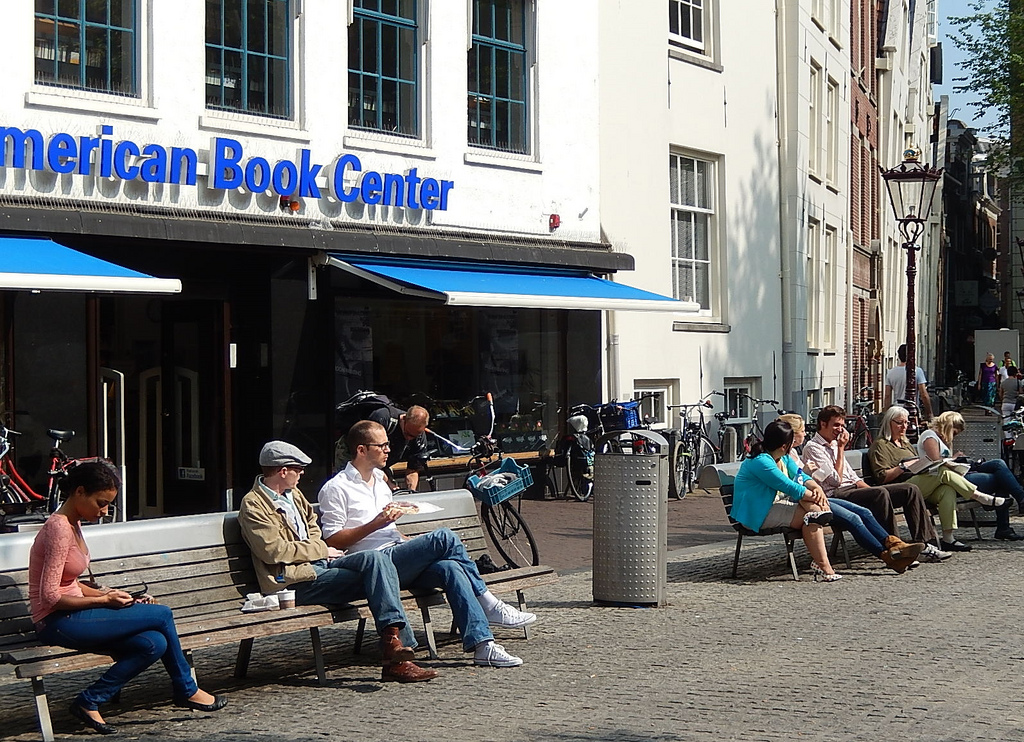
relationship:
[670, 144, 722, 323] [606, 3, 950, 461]
window on building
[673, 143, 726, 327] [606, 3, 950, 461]
window on building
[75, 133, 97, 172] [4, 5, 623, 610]
letters on building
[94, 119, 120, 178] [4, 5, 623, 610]
letters on building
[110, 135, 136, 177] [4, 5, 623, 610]
letters on building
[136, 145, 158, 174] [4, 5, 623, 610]
letters on building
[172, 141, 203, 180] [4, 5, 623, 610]
letters on building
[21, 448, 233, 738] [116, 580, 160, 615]
woman using phone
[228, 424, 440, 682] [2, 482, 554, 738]
men sitting on bench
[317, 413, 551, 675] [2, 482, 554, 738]
men sitting on bench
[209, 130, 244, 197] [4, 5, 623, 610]
letter above building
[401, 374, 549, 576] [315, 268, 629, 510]
bicycles against wall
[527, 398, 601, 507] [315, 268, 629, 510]
bicycles against wall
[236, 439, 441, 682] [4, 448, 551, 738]
men sat along bench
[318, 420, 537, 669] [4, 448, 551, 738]
men sat along bench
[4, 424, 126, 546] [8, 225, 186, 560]
bicycle against wall